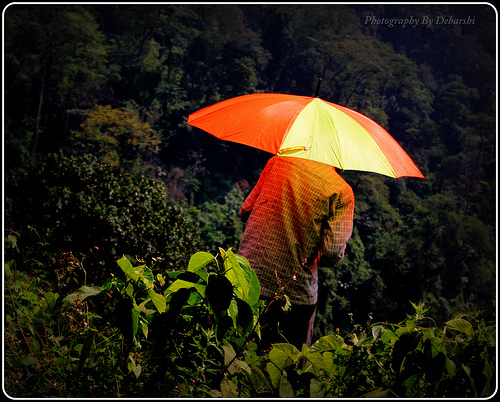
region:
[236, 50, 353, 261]
the umbrella is yellow and orange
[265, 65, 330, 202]
the umbrella is yellow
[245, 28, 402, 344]
the umbrella is yellow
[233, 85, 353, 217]
the umbrella is yellow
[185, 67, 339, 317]
the umbrella is yellow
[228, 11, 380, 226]
the umbrella is yellow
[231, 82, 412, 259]
An umbrella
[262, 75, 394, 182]
An umbrella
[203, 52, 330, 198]
An umbrella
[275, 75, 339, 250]
An umbrella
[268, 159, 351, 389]
An umbrella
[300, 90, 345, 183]
An umbrella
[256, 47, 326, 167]
An umbrella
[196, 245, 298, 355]
green leaf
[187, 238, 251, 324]
green leaf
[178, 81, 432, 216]
The umbrella is orange and yellow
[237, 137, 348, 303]
The person is wearing a brown and white shirt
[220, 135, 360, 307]
The shirt is checkered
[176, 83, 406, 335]
The person is holding an umbrella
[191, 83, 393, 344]
The person is walking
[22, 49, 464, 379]
The foliage is dense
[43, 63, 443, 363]
The foliage is green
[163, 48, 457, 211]
There are trees behind the person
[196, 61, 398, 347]
The person is walking through the foliage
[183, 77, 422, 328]
The person holds the umbrella to protect themselves from the sun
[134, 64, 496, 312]
An umbrella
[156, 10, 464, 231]
An umbrella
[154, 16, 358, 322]
An umbrella